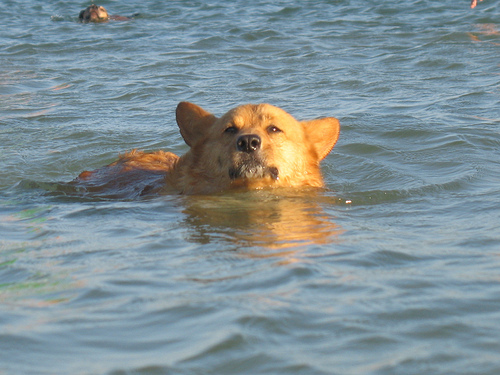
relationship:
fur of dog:
[292, 143, 309, 187] [107, 100, 343, 213]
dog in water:
[46, 95, 348, 220] [15, 26, 474, 346]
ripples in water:
[163, 303, 359, 363] [66, 225, 433, 344]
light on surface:
[278, 150, 323, 243] [172, 197, 357, 249]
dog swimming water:
[46, 95, 348, 220] [68, 256, 425, 349]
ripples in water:
[259, 252, 402, 340] [12, 268, 463, 276]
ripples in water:
[193, 299, 325, 362] [176, 294, 376, 364]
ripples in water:
[272, 292, 414, 368] [144, 224, 389, 338]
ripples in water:
[334, 293, 455, 338] [203, 290, 448, 373]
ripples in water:
[333, 297, 455, 373] [248, 236, 429, 369]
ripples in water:
[262, 287, 396, 365] [326, 278, 441, 368]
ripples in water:
[314, 297, 446, 363] [322, 282, 462, 359]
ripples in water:
[314, 297, 446, 363] [368, 278, 453, 370]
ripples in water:
[314, 297, 446, 363] [178, 289, 409, 355]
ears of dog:
[308, 108, 348, 165] [46, 95, 348, 220]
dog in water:
[46, 95, 348, 220] [248, 270, 475, 368]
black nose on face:
[234, 132, 263, 154] [213, 106, 295, 194]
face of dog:
[213, 106, 295, 194] [49, 100, 349, 227]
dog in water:
[46, 95, 348, 220] [315, 267, 447, 361]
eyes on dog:
[258, 119, 279, 139] [46, 95, 348, 220]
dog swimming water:
[46, 95, 348, 220] [284, 250, 456, 346]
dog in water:
[46, 95, 348, 220] [317, 309, 440, 373]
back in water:
[115, 142, 186, 178] [195, 268, 405, 355]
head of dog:
[171, 95, 343, 188] [53, 94, 342, 240]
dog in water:
[46, 95, 348, 220] [58, 231, 398, 372]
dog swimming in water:
[46, 95, 348, 220] [65, 242, 403, 372]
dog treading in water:
[46, 95, 348, 220] [35, 213, 462, 367]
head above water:
[162, 95, 342, 205] [55, 216, 498, 344]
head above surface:
[171, 95, 343, 188] [88, 183, 482, 332]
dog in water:
[68, 0, 127, 38] [33, 213, 438, 338]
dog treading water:
[47, 0, 129, 31] [14, 30, 200, 96]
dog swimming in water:
[47, 0, 129, 31] [3, 2, 499, 372]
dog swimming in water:
[46, 95, 348, 220] [3, 2, 499, 372]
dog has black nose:
[46, 95, 348, 220] [231, 128, 263, 157]